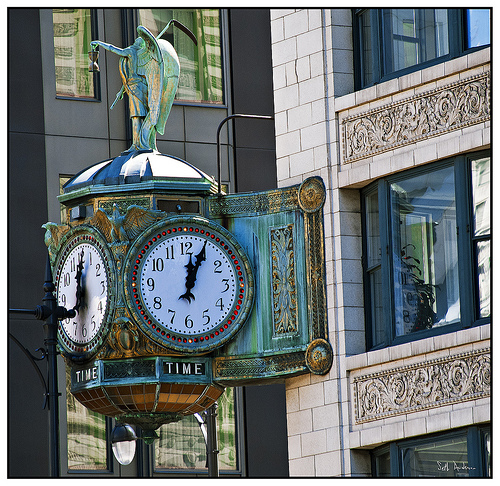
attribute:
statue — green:
[69, 21, 200, 219]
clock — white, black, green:
[43, 224, 118, 363]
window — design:
[352, 144, 481, 349]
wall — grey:
[234, 33, 284, 92]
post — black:
[119, 421, 177, 475]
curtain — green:
[360, 190, 418, 337]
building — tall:
[154, 41, 285, 216]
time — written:
[67, 354, 111, 398]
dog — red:
[229, 311, 248, 318]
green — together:
[229, 208, 311, 240]